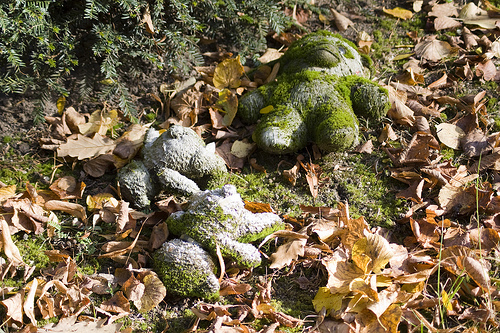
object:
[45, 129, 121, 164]
leaves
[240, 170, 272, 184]
algae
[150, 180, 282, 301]
doll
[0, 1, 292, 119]
tree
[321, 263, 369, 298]
leaves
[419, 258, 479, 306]
grass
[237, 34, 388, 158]
animal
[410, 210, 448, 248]
leaves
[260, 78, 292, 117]
algae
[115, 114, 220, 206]
animal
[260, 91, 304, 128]
moss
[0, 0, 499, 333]
ground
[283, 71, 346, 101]
moss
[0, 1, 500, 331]
yard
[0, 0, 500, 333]
woods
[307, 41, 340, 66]
mouth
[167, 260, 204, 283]
algae